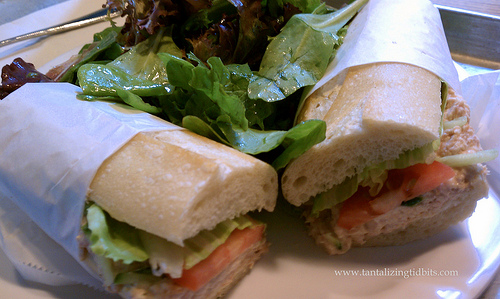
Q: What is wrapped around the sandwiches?
A: Paper.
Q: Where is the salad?
A: Between the two sandwiches.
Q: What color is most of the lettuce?
A: Green.